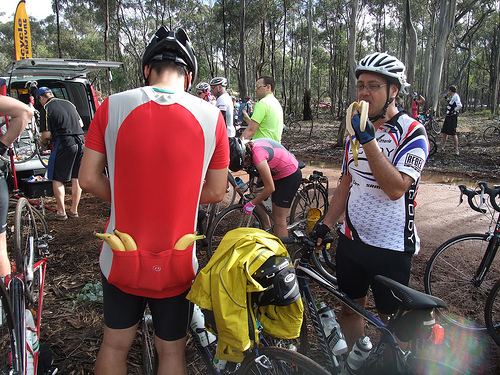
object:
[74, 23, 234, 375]
man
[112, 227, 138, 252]
bananas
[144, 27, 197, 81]
helmet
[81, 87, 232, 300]
shirt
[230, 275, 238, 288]
yellow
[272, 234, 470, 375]
bike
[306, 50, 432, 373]
man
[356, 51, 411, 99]
helmet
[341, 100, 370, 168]
banana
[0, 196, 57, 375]
bike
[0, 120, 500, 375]
ground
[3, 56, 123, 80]
door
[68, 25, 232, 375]
bicyclist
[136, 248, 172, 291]
pockets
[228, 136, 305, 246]
woman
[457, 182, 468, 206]
handbreaks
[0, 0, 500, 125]
woods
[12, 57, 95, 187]
vehicle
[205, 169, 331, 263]
bikes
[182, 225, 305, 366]
jacket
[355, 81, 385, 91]
glasses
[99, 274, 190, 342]
shorts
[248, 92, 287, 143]
shirt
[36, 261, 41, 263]
red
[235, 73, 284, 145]
people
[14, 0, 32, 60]
sign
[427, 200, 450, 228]
dirt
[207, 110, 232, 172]
sleeve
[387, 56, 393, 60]
white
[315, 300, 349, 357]
bottles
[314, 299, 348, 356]
water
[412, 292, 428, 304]
black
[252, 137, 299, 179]
shirt